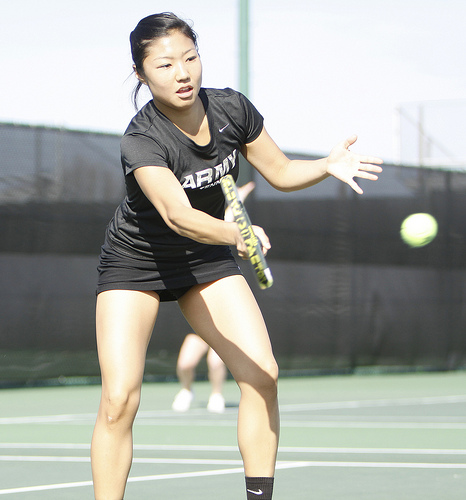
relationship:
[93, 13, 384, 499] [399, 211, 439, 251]
person hit a ball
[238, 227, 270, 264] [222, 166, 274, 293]
hand holding racket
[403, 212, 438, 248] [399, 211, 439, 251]
ball for ball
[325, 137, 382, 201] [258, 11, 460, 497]
hand on left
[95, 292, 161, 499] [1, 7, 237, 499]
leg on right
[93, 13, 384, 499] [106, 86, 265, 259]
person has on a shirt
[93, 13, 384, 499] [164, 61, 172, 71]
person has a eye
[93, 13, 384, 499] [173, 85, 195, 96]
person has a mouth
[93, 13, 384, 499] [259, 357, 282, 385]
person has a knee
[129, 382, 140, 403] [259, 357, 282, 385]
scar on right knee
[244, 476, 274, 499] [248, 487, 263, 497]
sock has a logo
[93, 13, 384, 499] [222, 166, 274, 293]
person has a racket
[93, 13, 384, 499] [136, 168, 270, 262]
person has an arm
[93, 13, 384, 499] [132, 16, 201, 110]
person has a head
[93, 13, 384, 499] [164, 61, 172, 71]
person has an eye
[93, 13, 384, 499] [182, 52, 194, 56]
person has an eyebrow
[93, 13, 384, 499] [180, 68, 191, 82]
person has a nose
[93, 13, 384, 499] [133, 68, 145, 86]
person has an ear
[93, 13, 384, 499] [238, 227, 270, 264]
person has a hand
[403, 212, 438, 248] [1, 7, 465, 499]
ball in air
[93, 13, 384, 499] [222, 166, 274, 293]
person holding racket